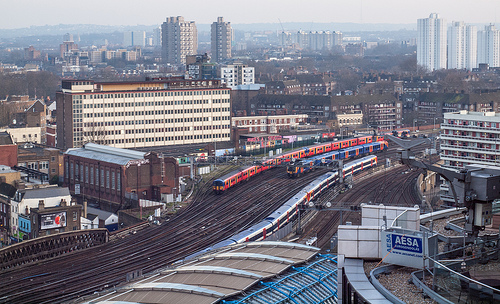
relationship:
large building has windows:
[55, 78, 232, 143] [154, 100, 164, 105]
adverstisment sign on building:
[39, 211, 67, 231] [29, 205, 80, 238]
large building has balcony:
[440, 110, 500, 169] [440, 122, 457, 129]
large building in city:
[55, 78, 232, 143] [0, 0, 496, 150]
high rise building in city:
[160, 16, 196, 72] [0, 0, 496, 150]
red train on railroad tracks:
[214, 135, 384, 189] [157, 195, 269, 240]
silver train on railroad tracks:
[251, 196, 319, 227] [157, 195, 269, 240]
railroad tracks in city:
[157, 195, 269, 240] [0, 0, 496, 150]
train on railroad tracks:
[293, 141, 390, 175] [157, 195, 269, 240]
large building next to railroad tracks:
[55, 78, 232, 143] [157, 195, 269, 240]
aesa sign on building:
[382, 230, 429, 272] [344, 201, 500, 302]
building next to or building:
[417, 19, 447, 72] [447, 26, 476, 70]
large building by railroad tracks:
[440, 110, 500, 169] [157, 195, 269, 240]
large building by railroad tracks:
[55, 78, 232, 143] [157, 195, 269, 240]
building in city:
[417, 19, 447, 72] [0, 0, 496, 150]